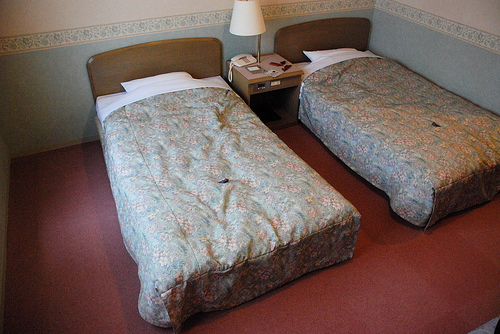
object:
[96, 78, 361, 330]
bed spread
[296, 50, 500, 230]
bed spread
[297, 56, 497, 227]
sheet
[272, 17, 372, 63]
board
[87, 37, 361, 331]
bed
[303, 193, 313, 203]
floral pattern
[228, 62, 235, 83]
cord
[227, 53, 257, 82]
phone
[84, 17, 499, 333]
twin bed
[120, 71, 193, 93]
pillow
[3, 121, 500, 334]
maroon carpet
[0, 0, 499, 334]
bedroom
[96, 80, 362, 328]
blanket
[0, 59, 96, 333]
left side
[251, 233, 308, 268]
spread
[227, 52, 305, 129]
small table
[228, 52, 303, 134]
table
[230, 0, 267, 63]
lamp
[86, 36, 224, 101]
board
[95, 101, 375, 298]
sheets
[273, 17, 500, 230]
bed